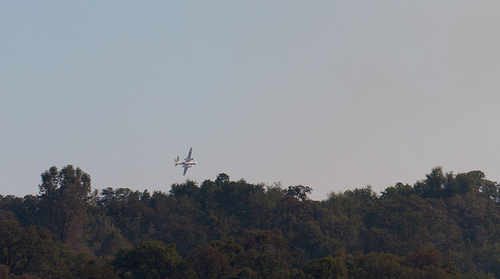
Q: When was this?
A: Daytime.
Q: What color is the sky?
A: Blue.